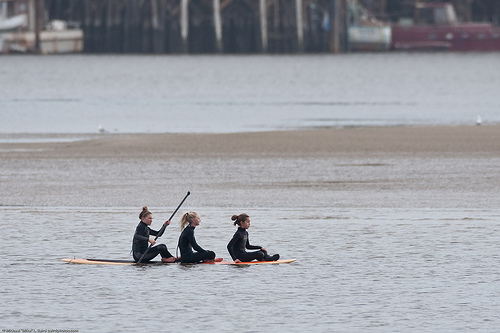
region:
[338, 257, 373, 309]
part of a water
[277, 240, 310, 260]
part of a board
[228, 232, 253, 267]
part of a cotume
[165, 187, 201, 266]
part fo a lady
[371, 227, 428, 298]
part of a water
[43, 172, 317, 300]
three women on a very long paddle board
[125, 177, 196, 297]
a woman holding a paddle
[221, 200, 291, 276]
a girl wearing a wet suit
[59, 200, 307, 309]
three girls in the ocean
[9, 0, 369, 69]
the pylons on a wooden pier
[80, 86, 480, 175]
a sand bank in the ocean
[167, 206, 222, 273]
a girl with blonde hair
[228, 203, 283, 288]
a girl in a pony tail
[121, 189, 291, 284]
three girls wearing wet suits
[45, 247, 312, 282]
a very long paddle board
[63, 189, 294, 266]
three women on a surfboard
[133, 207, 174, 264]
a woman sitting on a board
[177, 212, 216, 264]
a blond woman sitting on a board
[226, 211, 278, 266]
a woman sitting on a board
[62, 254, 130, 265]
the tail of a surfboard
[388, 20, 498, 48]
a red boat in the distance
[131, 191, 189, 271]
a woman holding an oar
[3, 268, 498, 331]
choppy water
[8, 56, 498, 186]
choppy water in the sea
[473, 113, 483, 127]
a small buoy in the distance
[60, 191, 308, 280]
Three women on a floating object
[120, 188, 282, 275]
Women are wearing wetsuits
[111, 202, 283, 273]
Wetsuits are black in color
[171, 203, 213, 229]
Woman in the middle has blonde hair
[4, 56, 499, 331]
A large body of water in the foreground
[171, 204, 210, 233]
Woman has her hair in a ponytail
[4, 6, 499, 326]
Photo was taken outdoors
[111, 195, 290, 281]
Women are sitting down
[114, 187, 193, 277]
Woman in the back is holding a pole object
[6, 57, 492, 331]
The water is gray in color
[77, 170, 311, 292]
three girls sitting on a board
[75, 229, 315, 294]
an orange board in the water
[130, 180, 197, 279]
a paddle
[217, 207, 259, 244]
brown hair on a girl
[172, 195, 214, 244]
blonde hair on a girl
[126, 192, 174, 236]
a bun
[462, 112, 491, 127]
birds on the land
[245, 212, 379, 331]
shallow water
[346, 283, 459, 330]
brown water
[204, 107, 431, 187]
sand between the pools of water